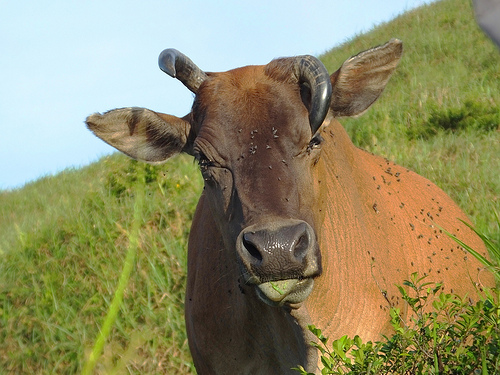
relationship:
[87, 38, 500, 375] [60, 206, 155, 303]
brown cow on grass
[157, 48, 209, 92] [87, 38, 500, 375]
black horns on brown cow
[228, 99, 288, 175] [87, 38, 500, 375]
files on brown cow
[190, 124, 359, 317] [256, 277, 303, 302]
bull's tongue bull's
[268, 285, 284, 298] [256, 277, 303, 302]
grass on bull's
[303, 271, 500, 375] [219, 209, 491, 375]
bush in front of bull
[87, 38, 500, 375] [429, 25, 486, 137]
brown cow sitting on field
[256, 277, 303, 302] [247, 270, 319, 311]
bull's sticking out mouth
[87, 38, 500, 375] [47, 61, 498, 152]
brown cow brown ears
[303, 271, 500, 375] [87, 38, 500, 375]
bush front of brown cow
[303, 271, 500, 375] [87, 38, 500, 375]
bush on brown cow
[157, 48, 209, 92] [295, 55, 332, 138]
black horns curved cow's horn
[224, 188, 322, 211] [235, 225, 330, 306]
brown cow tongue sticking out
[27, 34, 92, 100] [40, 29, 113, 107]
bright sunny day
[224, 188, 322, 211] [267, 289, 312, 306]
brown cow chasing food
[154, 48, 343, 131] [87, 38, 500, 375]
black horns on brown brown cow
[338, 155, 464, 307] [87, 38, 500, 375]
body of brown brown cow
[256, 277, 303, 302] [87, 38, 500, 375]
bull's of brown brown cow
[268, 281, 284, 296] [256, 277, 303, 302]
food on cows bull's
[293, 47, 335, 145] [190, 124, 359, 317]
cow's horn curving on face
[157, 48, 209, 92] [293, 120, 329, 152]
black horns curling into eye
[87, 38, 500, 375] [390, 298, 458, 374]
brown cow eating bush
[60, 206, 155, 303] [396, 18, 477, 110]
grass covering hillside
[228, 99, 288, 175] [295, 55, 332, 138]
files on cow's horn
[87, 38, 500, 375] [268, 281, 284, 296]
brown cow has grass food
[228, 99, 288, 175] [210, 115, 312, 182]
files on cows face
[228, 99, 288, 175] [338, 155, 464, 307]
files on cows body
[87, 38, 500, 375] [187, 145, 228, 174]
brown cow has flies in eye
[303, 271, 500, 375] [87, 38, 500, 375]
bush next to brown cow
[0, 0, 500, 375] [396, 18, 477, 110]
grass landscape behind cow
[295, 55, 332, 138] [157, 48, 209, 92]
cow's horn horns black horns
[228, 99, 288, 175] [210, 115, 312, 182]
files over face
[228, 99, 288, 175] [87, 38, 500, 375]
files over brown cow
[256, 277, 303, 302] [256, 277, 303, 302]
bull's green bull's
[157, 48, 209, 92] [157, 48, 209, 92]
black horns normal black horns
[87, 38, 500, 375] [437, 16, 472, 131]
brown cow standing on grassy hill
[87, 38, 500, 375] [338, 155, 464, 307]
brown cow brown and covered with flies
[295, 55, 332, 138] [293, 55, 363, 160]
cow's horn wrong and black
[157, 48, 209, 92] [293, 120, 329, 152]
black horns on  bulls eye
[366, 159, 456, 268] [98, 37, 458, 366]
files on side of bull